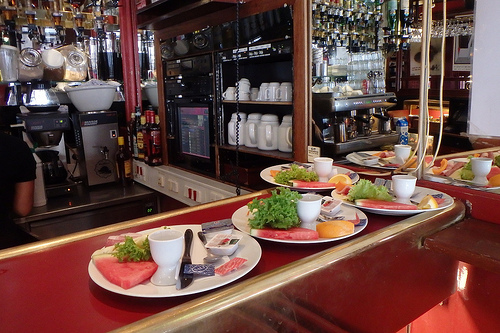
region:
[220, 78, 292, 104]
coffee cups on a shelf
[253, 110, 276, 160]
white water jugs on a shelf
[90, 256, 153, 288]
a slice of watermelon on a plate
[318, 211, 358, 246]
a slice of orange on a plate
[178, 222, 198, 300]
a silver butter knife on a plate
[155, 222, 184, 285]
a white cup on a plate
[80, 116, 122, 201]
a commercial coffee maker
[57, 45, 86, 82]
clear glass canister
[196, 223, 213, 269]
a silver spoon on a plate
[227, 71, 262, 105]
stacks of cups on a shelf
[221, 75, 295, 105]
the white mugs are upside down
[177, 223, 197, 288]
a knife is on the plate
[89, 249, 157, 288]
a slice of watermelon on a plate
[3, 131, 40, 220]
part of a person's arm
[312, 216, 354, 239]
an orange slice on a plate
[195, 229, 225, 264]
a spoon on a plate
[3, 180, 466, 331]
the counter top is red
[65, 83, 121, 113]
the bowl is big and white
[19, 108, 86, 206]
a coffee pot by the bowl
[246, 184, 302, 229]
green vegetable on a plate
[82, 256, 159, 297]
sliced watermelon on a plate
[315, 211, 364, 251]
sliced orange on a plate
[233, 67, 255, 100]
a stack of cups on a shelf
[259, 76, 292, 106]
white coffee cups on a shelf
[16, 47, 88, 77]
clear glass canisters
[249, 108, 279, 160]
white jugs on a shelf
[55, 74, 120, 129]
a large white bowl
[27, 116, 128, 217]
a coffee pot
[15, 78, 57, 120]
a coffee pot with coffee in it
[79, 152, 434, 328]
four plates of food on a counter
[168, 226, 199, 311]
silver knife on table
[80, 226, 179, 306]
watermelon on plate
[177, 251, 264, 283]
satchets on plate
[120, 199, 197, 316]
egg holder on plate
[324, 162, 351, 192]
lemon on plate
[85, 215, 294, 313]
round white plate on counter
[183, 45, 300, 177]
white cups and teapots on shelf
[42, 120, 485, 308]
plates on red counter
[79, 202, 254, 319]
plate on a table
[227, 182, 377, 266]
plate on a table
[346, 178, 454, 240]
plate on a table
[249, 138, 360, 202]
plate on a table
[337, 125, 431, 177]
plate on a table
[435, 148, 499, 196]
plate on a table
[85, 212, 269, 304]
white plate on a table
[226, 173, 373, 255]
white plate on a table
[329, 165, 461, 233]
white plate on a table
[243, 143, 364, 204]
white plate on a table